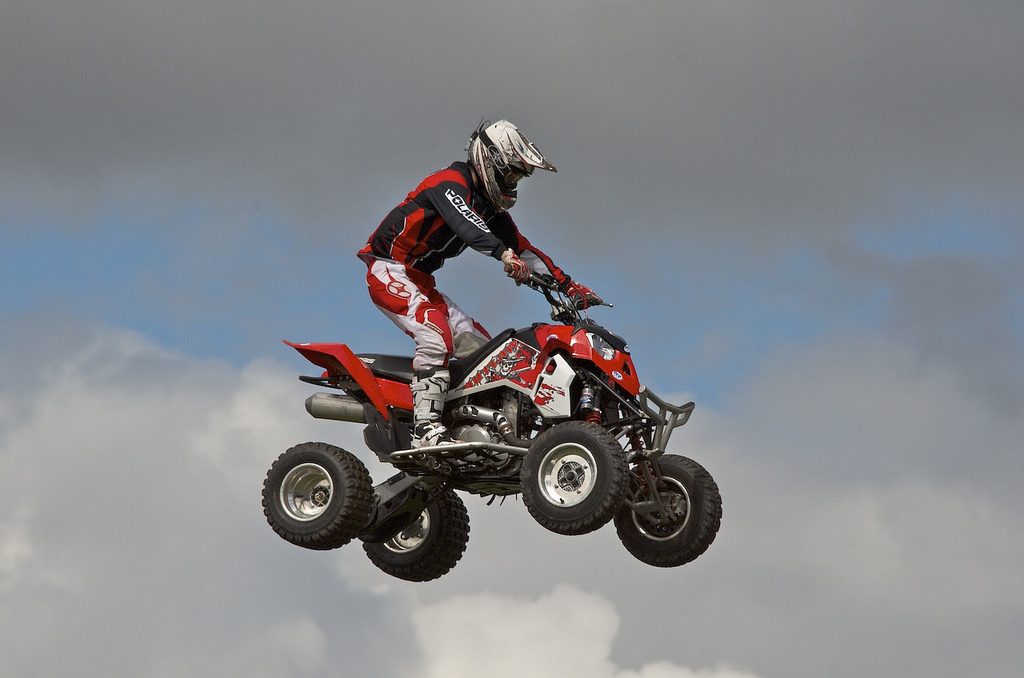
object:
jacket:
[358, 161, 572, 293]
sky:
[0, 201, 1021, 410]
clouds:
[0, 323, 1024, 678]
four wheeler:
[262, 420, 722, 582]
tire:
[520, 421, 630, 537]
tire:
[614, 454, 723, 568]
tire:
[262, 442, 375, 550]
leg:
[365, 258, 453, 422]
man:
[354, 117, 601, 448]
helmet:
[465, 117, 558, 213]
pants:
[365, 260, 493, 424]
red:
[358, 165, 468, 268]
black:
[429, 181, 522, 261]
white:
[370, 260, 449, 447]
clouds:
[0, 0, 1024, 237]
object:
[261, 265, 721, 582]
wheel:
[359, 474, 469, 582]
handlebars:
[504, 264, 613, 326]